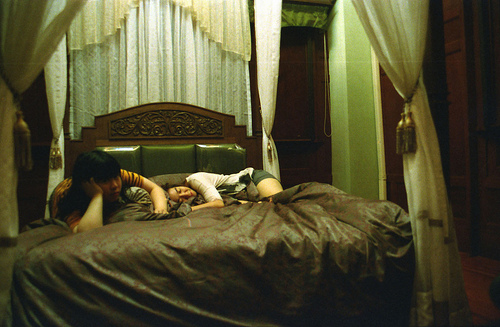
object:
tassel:
[394, 125, 418, 155]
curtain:
[344, 0, 470, 325]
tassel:
[13, 131, 35, 175]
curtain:
[0, 0, 82, 247]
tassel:
[50, 155, 65, 171]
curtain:
[41, 32, 70, 222]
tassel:
[266, 150, 277, 165]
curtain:
[248, 0, 283, 191]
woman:
[160, 166, 282, 211]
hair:
[160, 185, 187, 191]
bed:
[10, 100, 418, 327]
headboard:
[69, 102, 258, 187]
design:
[105, 109, 228, 140]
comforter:
[9, 172, 415, 326]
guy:
[48, 148, 171, 234]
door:
[241, 21, 340, 195]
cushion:
[194, 142, 246, 176]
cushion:
[141, 142, 199, 177]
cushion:
[93, 144, 142, 175]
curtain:
[68, 0, 253, 142]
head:
[69, 149, 123, 202]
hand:
[81, 177, 104, 197]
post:
[246, 0, 262, 137]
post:
[60, 22, 72, 145]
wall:
[325, 0, 385, 211]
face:
[167, 186, 197, 203]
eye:
[178, 188, 182, 194]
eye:
[181, 198, 184, 202]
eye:
[113, 174, 119, 179]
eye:
[103, 179, 110, 183]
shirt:
[184, 167, 256, 203]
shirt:
[48, 169, 147, 231]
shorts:
[246, 168, 279, 186]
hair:
[52, 150, 124, 220]